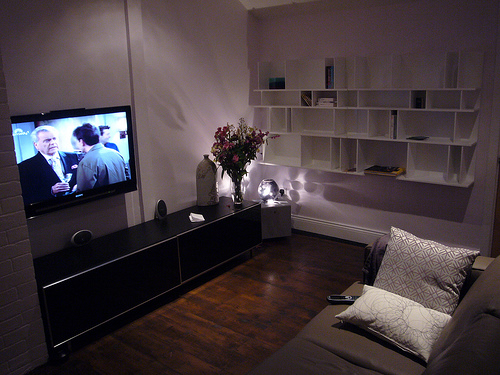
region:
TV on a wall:
[9, 109, 139, 199]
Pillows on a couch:
[363, 218, 450, 370]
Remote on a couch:
[318, 280, 373, 320]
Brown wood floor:
[137, 301, 282, 373]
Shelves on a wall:
[234, 51, 476, 200]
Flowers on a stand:
[199, 111, 265, 196]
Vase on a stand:
[180, 145, 227, 223]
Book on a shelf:
[362, 149, 396, 199]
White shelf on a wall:
[235, 71, 464, 193]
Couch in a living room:
[331, 224, 483, 373]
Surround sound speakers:
[57, 192, 174, 247]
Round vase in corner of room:
[254, 175, 280, 201]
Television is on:
[13, 105, 155, 205]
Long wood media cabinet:
[41, 204, 264, 337]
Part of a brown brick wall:
[1, 152, 46, 366]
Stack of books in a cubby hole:
[315, 92, 340, 109]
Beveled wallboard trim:
[296, 210, 373, 245]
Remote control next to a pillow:
[324, 288, 364, 307]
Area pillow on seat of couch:
[342, 286, 448, 348]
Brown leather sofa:
[261, 262, 497, 370]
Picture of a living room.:
[12, 14, 480, 365]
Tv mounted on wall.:
[13, 97, 143, 210]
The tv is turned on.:
[8, 96, 150, 213]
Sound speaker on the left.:
[59, 220, 107, 252]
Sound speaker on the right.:
[146, 194, 173, 227]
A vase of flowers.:
[206, 108, 268, 216]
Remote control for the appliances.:
[324, 281, 366, 311]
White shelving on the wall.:
[248, 43, 481, 194]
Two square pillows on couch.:
[331, 207, 482, 367]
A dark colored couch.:
[270, 217, 499, 374]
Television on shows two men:
[2, 97, 144, 215]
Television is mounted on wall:
[8, 90, 148, 221]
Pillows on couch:
[325, 220, 482, 362]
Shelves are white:
[233, 40, 493, 195]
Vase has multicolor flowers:
[203, 111, 270, 217]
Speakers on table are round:
[65, 193, 176, 259]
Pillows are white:
[330, 216, 485, 366]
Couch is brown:
[242, 222, 497, 370]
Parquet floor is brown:
[170, 255, 300, 360]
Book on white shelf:
[352, 158, 404, 183]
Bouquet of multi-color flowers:
[207, 121, 272, 182]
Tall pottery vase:
[192, 150, 222, 209]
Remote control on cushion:
[326, 291, 369, 306]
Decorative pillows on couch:
[338, 225, 480, 361]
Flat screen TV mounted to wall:
[11, 110, 146, 219]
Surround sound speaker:
[61, 228, 93, 244]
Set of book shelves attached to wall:
[255, 57, 472, 173]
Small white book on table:
[187, 207, 209, 224]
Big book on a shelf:
[363, 157, 405, 178]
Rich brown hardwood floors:
[97, 235, 343, 350]